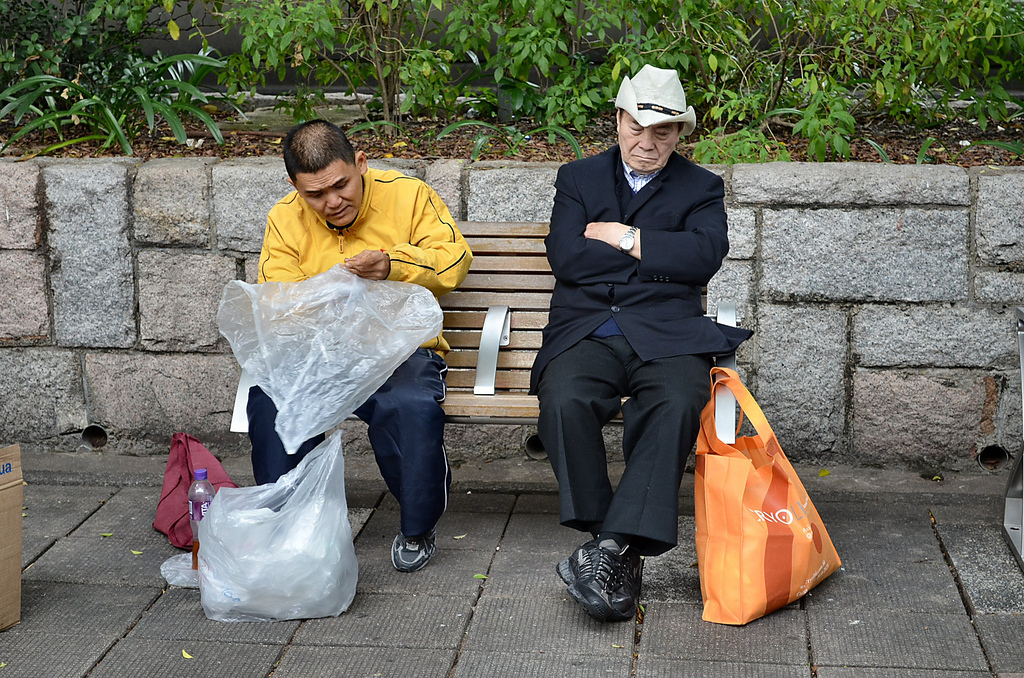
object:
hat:
[609, 61, 698, 138]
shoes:
[381, 513, 439, 579]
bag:
[207, 258, 452, 457]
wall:
[0, 150, 1024, 508]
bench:
[221, 214, 747, 454]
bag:
[681, 362, 857, 627]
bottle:
[178, 459, 224, 558]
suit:
[519, 148, 746, 556]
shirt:
[239, 166, 482, 369]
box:
[0, 440, 41, 623]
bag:
[144, 423, 253, 555]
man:
[214, 115, 478, 578]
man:
[521, 58, 766, 630]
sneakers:
[549, 533, 651, 628]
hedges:
[0, 0, 1024, 163]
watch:
[615, 224, 642, 258]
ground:
[0, 447, 1024, 678]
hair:
[278, 118, 358, 189]